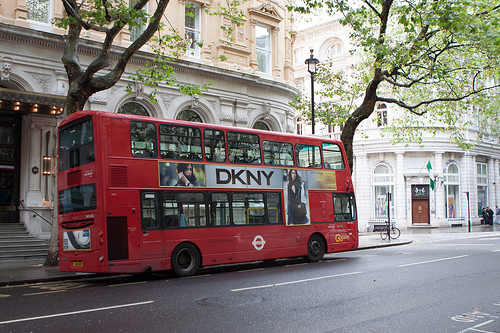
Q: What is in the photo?
A: A bus.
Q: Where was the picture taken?
A: A city.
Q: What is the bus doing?
A: Parked.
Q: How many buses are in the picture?
A: One.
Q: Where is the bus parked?
A: Beside the curb.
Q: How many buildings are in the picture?
A: Two.